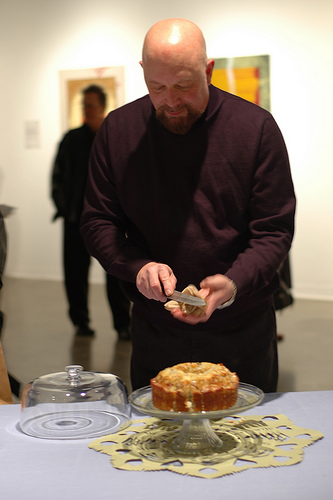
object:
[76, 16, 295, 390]
man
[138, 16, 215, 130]
head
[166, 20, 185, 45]
spot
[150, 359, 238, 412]
cake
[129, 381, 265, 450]
server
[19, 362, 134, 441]
lid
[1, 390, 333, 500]
table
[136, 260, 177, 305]
hand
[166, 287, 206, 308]
knife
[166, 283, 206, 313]
slice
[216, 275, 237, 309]
watch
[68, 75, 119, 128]
painting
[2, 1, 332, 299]
wall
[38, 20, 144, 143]
light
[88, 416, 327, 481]
placemat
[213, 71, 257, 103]
picture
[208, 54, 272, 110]
frame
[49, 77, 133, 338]
man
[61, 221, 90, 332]
leg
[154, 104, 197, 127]
moustache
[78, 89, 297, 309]
shirt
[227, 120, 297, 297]
sleeve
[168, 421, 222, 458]
pedestal